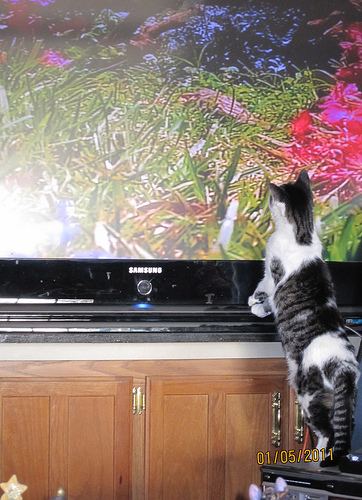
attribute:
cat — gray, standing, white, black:
[248, 168, 360, 468]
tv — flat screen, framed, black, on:
[0, 0, 362, 333]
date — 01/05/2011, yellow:
[256, 447, 334, 465]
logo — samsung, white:
[129, 267, 163, 273]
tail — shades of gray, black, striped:
[320, 371, 354, 467]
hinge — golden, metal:
[136, 387, 146, 414]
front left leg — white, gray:
[247, 261, 281, 307]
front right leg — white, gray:
[251, 296, 272, 318]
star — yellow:
[0, 473, 28, 499]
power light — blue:
[136, 303, 150, 309]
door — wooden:
[0, 375, 133, 499]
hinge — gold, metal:
[132, 387, 137, 414]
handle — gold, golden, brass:
[272, 391, 282, 446]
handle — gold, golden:
[294, 397, 304, 444]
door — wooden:
[142, 374, 291, 500]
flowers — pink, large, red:
[0, 0, 362, 262]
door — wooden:
[289, 386, 319, 461]